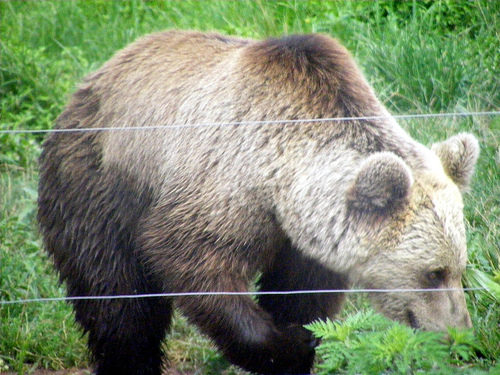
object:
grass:
[299, 312, 500, 375]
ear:
[350, 150, 413, 210]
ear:
[426, 131, 477, 188]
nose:
[454, 318, 474, 342]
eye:
[425, 265, 448, 285]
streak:
[238, 33, 394, 155]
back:
[37, 29, 374, 187]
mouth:
[399, 305, 426, 345]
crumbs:
[131, 290, 138, 297]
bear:
[36, 31, 481, 375]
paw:
[243, 325, 317, 375]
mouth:
[396, 303, 425, 330]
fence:
[0, 110, 500, 306]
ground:
[0, 0, 500, 375]